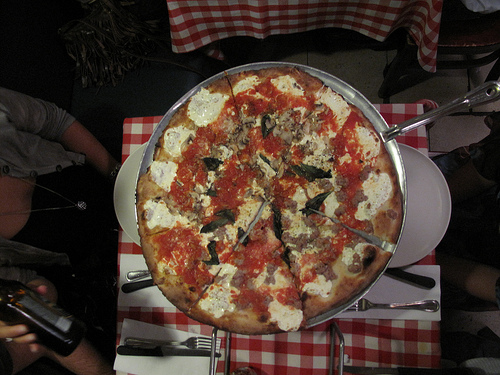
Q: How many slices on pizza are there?
A: 8.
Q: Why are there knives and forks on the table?
A: To eat with.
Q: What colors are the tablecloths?
A: Red and white.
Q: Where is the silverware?
A: On napkins.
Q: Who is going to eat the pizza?
A: The people are the table.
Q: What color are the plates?
A: Red.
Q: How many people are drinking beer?
A: 1.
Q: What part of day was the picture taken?
A: At night.